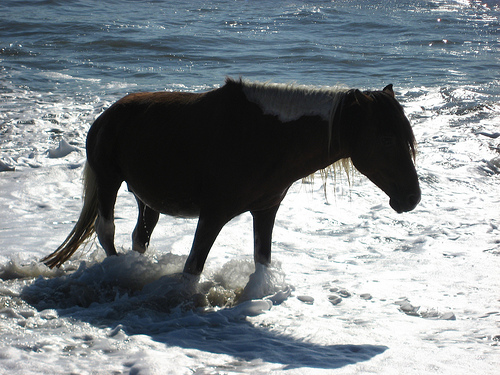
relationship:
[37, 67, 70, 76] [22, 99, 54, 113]
foam in sea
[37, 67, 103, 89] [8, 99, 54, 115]
foam in sea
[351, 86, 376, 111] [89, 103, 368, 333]
ear of horse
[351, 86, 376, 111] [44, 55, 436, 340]
ear of horse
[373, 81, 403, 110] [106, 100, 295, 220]
ear of horse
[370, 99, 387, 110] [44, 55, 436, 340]
ear of horse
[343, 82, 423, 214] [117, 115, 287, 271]
head of horse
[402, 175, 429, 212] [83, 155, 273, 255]
nose of horse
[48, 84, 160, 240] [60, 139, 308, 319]
rear of horse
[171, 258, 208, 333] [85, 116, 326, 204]
leg of horse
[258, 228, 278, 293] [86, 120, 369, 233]
leg of horse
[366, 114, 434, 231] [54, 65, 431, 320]
head of horse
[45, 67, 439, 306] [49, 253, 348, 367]
horse in water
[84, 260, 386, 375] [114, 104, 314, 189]
shadow of horse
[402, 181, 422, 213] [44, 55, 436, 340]
nose of horse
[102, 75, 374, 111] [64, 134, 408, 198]
back of horse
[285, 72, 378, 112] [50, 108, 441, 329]
hair on head of horse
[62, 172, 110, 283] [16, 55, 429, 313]
tail of horse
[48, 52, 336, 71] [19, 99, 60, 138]
ripples in water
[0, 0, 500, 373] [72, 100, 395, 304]
sea near horse